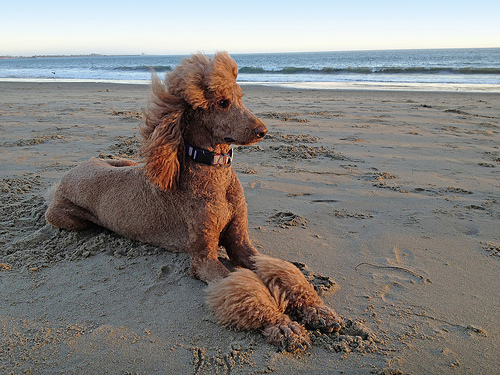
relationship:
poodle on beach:
[44, 51, 340, 351] [1, 72, 499, 373]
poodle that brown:
[44, 51, 340, 351] [123, 194, 190, 230]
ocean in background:
[0, 45, 499, 80] [0, 0, 499, 79]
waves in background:
[92, 62, 499, 74] [0, 0, 499, 79]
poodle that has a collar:
[44, 51, 340, 351] [184, 136, 234, 166]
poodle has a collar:
[44, 51, 340, 351] [184, 136, 234, 166]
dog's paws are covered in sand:
[263, 298, 340, 350] [310, 315, 375, 357]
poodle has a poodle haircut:
[44, 51, 340, 351] [45, 48, 342, 348]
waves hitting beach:
[92, 62, 499, 74] [1, 72, 499, 373]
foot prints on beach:
[269, 209, 308, 227] [1, 72, 499, 373]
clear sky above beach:
[0, 0, 499, 57] [1, 72, 499, 373]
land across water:
[0, 51, 149, 57] [0, 45, 499, 80]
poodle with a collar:
[44, 51, 340, 351] [184, 136, 234, 166]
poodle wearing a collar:
[44, 51, 340, 351] [184, 136, 234, 166]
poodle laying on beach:
[44, 51, 340, 351] [1, 72, 499, 373]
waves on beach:
[92, 62, 499, 74] [1, 72, 499, 373]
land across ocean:
[0, 51, 149, 57] [0, 45, 499, 80]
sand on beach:
[310, 315, 375, 357] [1, 72, 499, 373]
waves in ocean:
[92, 62, 499, 74] [0, 45, 499, 80]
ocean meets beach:
[0, 45, 499, 80] [1, 72, 499, 373]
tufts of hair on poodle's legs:
[201, 255, 320, 327] [187, 215, 341, 349]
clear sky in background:
[0, 0, 499, 57] [0, 0, 499, 79]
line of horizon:
[0, 52, 499, 62] [0, 55, 498, 59]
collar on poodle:
[184, 136, 234, 166] [44, 51, 340, 351]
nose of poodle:
[252, 124, 268, 140] [44, 51, 340, 351]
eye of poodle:
[217, 96, 231, 111] [44, 51, 340, 351]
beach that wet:
[1, 72, 499, 373] [0, 77, 498, 96]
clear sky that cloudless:
[0, 0, 499, 57] [0, 0, 499, 79]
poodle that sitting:
[44, 51, 340, 351] [43, 158, 139, 233]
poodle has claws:
[44, 51, 340, 351] [279, 338, 309, 349]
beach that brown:
[1, 72, 499, 373] [29, 260, 147, 340]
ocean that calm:
[0, 45, 499, 80] [0, 47, 499, 66]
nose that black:
[252, 124, 268, 140] [260, 126, 265, 131]